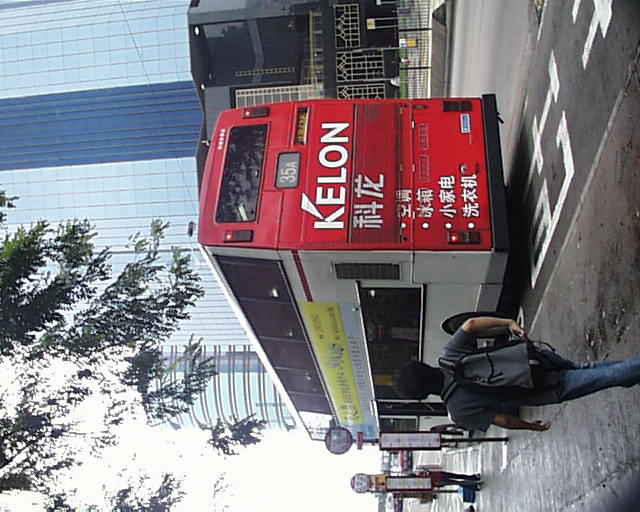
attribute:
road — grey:
[461, 8, 629, 259]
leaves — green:
[1, 261, 81, 338]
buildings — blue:
[0, 14, 347, 453]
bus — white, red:
[162, 91, 569, 414]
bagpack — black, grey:
[448, 350, 556, 404]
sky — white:
[2, 343, 388, 510]